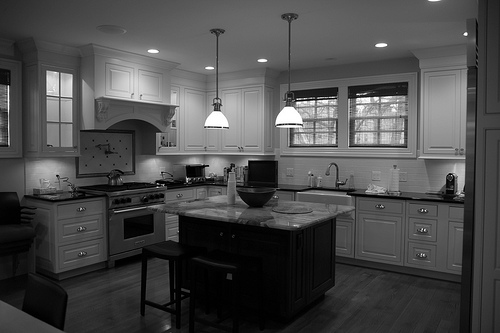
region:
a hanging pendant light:
[275, 13, 303, 127]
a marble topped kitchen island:
[150, 189, 352, 313]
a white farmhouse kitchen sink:
[295, 185, 350, 210]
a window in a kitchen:
[344, 81, 409, 148]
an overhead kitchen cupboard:
[412, 45, 467, 164]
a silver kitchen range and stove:
[78, 180, 166, 270]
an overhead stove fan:
[80, 41, 178, 140]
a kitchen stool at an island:
[133, 239, 188, 321]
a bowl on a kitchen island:
[233, 184, 278, 209]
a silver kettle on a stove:
[105, 168, 123, 187]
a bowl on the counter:
[229, 172, 285, 207]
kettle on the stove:
[84, 153, 164, 206]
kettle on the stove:
[99, 162, 138, 207]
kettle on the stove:
[102, 159, 129, 184]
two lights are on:
[168, 50, 366, 171]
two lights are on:
[182, 101, 327, 143]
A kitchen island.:
[152, 192, 354, 325]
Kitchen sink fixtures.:
[322, 160, 347, 190]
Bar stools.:
[139, 242, 253, 331]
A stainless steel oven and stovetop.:
[83, 178, 176, 266]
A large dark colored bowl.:
[234, 186, 275, 206]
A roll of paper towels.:
[387, 164, 399, 189]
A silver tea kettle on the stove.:
[104, 166, 129, 187]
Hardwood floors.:
[2, 243, 462, 329]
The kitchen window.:
[286, 86, 412, 153]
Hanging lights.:
[204, 14, 306, 129]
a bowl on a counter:
[176, 127, 347, 273]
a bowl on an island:
[128, 91, 394, 315]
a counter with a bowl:
[171, 118, 361, 295]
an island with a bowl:
[112, 139, 324, 328]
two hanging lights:
[179, 11, 350, 166]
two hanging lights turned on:
[179, 11, 371, 180]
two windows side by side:
[276, 54, 494, 157]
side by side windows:
[265, 51, 428, 176]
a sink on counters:
[282, 136, 476, 284]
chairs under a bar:
[132, 191, 315, 329]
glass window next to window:
[285, 86, 338, 146]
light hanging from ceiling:
[205, 25, 227, 125]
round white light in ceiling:
[145, 45, 157, 51]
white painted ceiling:
[1, 0, 471, 75]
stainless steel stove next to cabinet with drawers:
[76, 180, 161, 265]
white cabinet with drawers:
[17, 190, 102, 275]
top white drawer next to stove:
[55, 195, 105, 217]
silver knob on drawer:
[72, 202, 82, 208]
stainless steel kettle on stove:
[101, 165, 121, 185]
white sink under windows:
[292, 185, 353, 216]